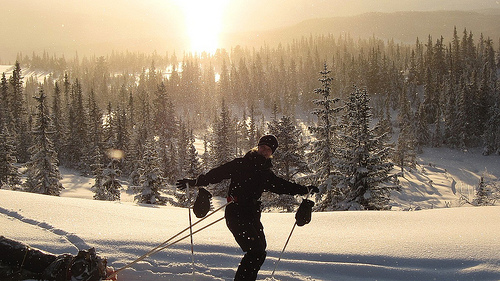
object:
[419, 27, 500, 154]
trees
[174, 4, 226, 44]
sun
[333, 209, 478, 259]
buds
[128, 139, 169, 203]
tree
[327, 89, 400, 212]
tree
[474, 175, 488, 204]
tree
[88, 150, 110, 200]
tree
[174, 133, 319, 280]
man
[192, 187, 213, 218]
gloves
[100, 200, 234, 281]
pole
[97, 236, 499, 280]
shadow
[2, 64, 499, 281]
ground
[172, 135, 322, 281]
person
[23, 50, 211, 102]
trees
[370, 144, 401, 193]
branches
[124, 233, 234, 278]
tracks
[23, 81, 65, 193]
tree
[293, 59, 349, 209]
tree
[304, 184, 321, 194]
ski hand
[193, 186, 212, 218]
bags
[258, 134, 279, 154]
skier's hat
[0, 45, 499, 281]
snow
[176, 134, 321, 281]
woman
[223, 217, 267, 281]
pants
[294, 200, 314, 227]
glove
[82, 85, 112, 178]
tree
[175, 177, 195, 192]
hand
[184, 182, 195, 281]
ski pole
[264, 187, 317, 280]
ski pole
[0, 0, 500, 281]
mountain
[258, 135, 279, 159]
head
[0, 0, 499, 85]
sky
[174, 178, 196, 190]
gloves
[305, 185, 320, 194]
gloves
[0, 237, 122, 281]
sled